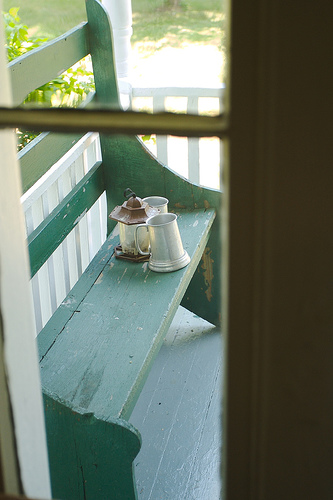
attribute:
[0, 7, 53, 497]
drape — white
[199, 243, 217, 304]
peeling — paint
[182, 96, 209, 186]
rail — wood, white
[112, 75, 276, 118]
railing — pouch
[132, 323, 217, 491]
floor — gray wooden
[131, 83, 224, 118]
railiing — white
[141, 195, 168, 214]
mug — drinking, metal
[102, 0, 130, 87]
post — porch wooden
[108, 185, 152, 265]
feeder — bird 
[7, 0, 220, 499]
bench — green 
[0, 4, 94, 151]
bush —  leafy green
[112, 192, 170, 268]
feeder — small, bird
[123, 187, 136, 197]
hook — black 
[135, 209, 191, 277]
mug — silver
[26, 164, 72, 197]
bannister — white , wood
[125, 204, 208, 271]
cup — silver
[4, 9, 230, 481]
bench — green , weather worn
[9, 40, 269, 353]
bench — outdoor, wooden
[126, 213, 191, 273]
mug — metal, drinking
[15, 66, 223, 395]
wooden bench — green wooden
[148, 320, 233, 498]
deck — blue, wood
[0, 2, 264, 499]
panel — wooden window 